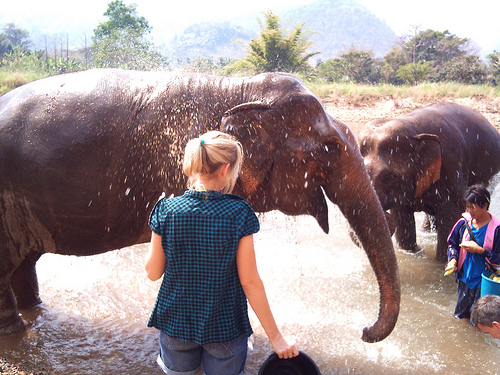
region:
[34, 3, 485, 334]
Picture taken outside.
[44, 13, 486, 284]
Picture taken during the day.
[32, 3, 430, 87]
The sun is out.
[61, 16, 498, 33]
The skies are bright white in color.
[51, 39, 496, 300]
Two elephants in the water.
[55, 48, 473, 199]
The elephants are brown.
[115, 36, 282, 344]
A woman standing next to an elephant.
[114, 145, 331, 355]
The woman is in the water.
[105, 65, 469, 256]
Water splashes against the elephants.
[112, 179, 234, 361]
The woman is wearing a short sleeved shirt.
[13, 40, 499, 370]
bath time for the elephants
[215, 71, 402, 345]
the elephant is happy and smiling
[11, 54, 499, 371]
the elephants love their bath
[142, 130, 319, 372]
the lady is holding a bucket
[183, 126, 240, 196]
the girl has a blonde ponytail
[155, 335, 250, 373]
the girl is wearing blue jean shorts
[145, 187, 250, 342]
the girl is wearing a checkered blouse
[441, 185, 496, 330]
a lady has a blue bucket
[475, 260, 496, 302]
sponges and brushes are in the blue bucket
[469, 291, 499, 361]
a man is bending down towards the water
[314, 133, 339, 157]
the eye of an elephant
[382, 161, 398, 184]
the eye of an elephant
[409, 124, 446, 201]
the ear of an elephant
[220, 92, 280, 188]
the ear of an elephant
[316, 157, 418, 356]
the trunk of an elephant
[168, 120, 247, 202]
the head of a person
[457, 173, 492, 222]
the head of a person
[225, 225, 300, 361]
the head of a person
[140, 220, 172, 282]
the head of a person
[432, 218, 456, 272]
the head of a person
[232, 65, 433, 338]
Water spraying from an elephant's trunk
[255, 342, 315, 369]
A black bucket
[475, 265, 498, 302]
A blue bucket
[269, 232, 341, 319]
Light shining brightly on water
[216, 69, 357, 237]
A happy elephant with its mouth open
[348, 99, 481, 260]
An elephant standing in water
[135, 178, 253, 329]
A plaid shirt on a woman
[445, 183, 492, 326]
A person standing in water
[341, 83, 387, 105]
Tall waving grass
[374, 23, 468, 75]
A group of trees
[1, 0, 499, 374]
two elephants getting a bath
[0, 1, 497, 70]
tall vegetation in the distance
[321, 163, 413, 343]
an elephants trunk is used for many tasks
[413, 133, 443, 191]
the elephants ears are two colors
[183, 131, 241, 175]
a ladies blond hair with a green rubber band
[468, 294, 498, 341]
a man splashing the elephants with water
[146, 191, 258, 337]
the ladies black and green checkered blouse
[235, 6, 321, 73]
a palm tree past the watering pond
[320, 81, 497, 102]
tall grazing grass at the foot of the watering hole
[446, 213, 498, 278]
a lady wearing a blue and pink jacket